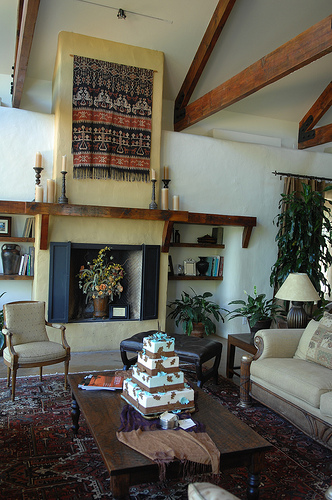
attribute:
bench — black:
[118, 327, 224, 379]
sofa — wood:
[239, 312, 330, 448]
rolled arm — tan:
[241, 324, 303, 405]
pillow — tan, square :
[295, 311, 331, 364]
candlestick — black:
[31, 148, 181, 213]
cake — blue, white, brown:
[121, 318, 197, 416]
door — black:
[51, 241, 159, 323]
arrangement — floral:
[77, 245, 123, 314]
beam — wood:
[172, 0, 324, 133]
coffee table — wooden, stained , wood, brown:
[64, 367, 274, 497]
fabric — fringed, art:
[69, 51, 157, 184]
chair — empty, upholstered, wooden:
[0, 298, 72, 399]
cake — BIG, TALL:
[117, 327, 195, 421]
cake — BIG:
[120, 328, 194, 409]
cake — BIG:
[118, 330, 194, 416]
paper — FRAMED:
[108, 305, 128, 321]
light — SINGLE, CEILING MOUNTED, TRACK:
[78, 4, 182, 29]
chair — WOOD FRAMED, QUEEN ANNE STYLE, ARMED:
[4, 294, 75, 405]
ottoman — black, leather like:
[118, 329, 225, 394]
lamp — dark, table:
[273, 272, 324, 331]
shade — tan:
[271, 269, 325, 307]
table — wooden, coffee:
[64, 365, 274, 499]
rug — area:
[1, 356, 328, 497]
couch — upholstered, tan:
[230, 316, 330, 451]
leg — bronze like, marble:
[236, 355, 254, 408]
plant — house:
[165, 289, 230, 341]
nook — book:
[160, 220, 231, 366]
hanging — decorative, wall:
[71, 50, 161, 189]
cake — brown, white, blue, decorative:
[121, 326, 203, 418]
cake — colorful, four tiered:
[117, 333, 203, 418]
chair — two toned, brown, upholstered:
[2, 302, 76, 400]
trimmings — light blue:
[147, 330, 168, 344]